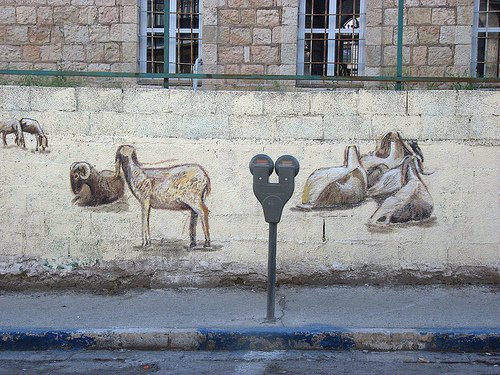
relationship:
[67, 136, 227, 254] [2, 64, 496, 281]
drawings on wall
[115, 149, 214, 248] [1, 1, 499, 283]
animal drawing on wall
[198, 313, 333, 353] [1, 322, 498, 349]
painting on curb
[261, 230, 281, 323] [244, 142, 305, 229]
pole on meter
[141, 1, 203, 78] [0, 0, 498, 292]
window on building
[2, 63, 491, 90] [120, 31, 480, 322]
pole above wall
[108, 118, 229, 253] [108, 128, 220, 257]
drawing of goat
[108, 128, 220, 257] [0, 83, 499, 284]
goat on wall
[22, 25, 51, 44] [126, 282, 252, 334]
brick with cracks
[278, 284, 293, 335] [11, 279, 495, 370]
crack in sidewalk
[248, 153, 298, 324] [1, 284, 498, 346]
parking meter on sidewalk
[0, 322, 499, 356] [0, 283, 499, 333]
paint on gray sidewalk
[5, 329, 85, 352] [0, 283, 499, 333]
paint on gray sidewalk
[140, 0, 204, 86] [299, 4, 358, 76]
window with bars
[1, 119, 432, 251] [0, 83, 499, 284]
rams painted on wall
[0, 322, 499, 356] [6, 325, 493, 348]
paint on curb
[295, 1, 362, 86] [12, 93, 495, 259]
window above wall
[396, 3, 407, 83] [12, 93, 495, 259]
pole above wall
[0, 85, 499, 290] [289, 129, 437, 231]
mural of goats